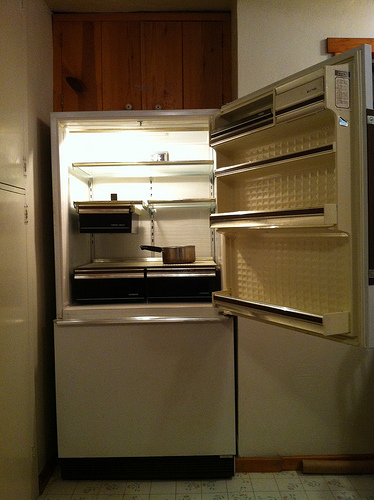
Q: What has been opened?
A: The refrigerator.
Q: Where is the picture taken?
A: A kitchen.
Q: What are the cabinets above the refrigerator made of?
A: Wood.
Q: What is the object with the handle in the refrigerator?
A: A pot.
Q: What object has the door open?
A: A refrigerator.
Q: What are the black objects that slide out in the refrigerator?
A: Drawers.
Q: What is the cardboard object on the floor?
A: A paper towel roll.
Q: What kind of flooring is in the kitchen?
A: Linoleum.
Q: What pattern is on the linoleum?
A: Floral.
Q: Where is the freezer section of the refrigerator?
A: On the bottom.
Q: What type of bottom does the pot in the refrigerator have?
A: Copper.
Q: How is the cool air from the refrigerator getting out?
A: Through the open door.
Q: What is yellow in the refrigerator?
A: Shelves.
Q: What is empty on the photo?
A: Refrigerator.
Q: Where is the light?
A: Inside refrigerator.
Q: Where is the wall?
A: Beside the refrigerator.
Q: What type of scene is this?
A: Indoor.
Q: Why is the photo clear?
A: Room is well lit.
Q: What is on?
A: Fridge light.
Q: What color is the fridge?
A: White.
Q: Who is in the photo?
A: No one.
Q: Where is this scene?
A: Kitchen.